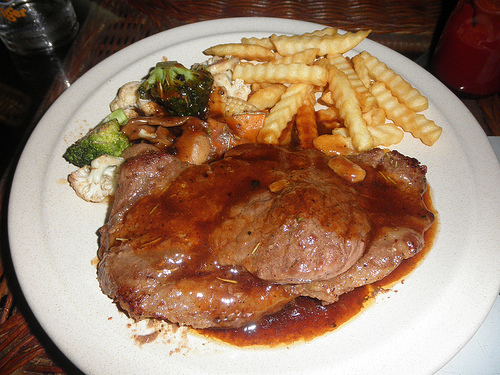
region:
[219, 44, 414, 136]
French fries on the plate.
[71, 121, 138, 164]
Broccoli on the plate.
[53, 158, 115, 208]
Cauliflower on the plate.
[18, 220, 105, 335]
The plate is white.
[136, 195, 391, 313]
Meat on the plate.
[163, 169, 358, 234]
Sauce over the meat.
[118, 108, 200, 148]
Mushrooms on the plate.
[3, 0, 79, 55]
Glass on the table.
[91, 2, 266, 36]
The table is wicker.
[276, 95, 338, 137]
Sauce on the fries.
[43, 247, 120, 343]
the plate is white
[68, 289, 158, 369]
the plate is white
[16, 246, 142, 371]
the plate is white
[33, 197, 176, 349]
the plate is white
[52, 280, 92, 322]
the plate is white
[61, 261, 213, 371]
the plate is white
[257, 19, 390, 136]
There are french fries on the plate.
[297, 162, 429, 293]
The meat has gravy over it.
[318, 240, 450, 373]
The plate is white.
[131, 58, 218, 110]
There is broccoli on the plate.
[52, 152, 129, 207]
There is cauliflower on the plate.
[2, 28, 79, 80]
The is a glass on the table.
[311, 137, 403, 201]
There is gravy on the french fries.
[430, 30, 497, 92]
There is a red sauce in the jar.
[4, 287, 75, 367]
The white plate is setting on a wood surface.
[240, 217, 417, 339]
The beef is sliced.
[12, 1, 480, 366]
a white plate with food on a table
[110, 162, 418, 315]
a juicy steak with sauce on top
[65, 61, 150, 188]
grilled broccoli and cauliflower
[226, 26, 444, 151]
a serving of fries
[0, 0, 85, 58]
an empty glass on a table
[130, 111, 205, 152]
grilled mushrooms with sauce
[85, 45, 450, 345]
a plate with steak, fries and veggies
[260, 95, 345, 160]
sauce on fries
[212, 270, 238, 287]
a bit of dry herb on a steak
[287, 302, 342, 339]
brown sauce on a white plate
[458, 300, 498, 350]
white edge of plate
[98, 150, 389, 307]
steak with sauce on it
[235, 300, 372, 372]
sauce under the steak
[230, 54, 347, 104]
crinkle french fries by steak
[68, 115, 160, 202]
cauliflower with the brocolli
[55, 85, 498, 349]
plate with food on it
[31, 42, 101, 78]
brown design on table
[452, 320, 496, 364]
napkin under the plate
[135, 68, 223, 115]
sauce on the brocolli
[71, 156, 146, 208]
white cauliflower on plate